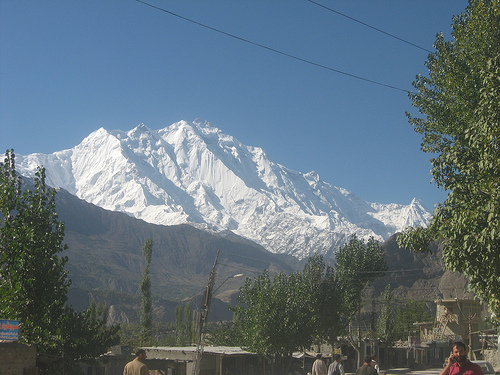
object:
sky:
[4, 0, 497, 204]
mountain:
[6, 116, 493, 295]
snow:
[272, 203, 353, 230]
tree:
[393, 23, 498, 277]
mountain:
[1, 282, 431, 333]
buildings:
[320, 319, 408, 373]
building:
[117, 333, 273, 373]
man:
[118, 348, 152, 374]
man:
[308, 353, 328, 374]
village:
[1, 297, 498, 374]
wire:
[120, 0, 400, 93]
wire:
[294, 0, 442, 56]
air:
[12, 3, 437, 184]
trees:
[189, 249, 224, 337]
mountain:
[166, 110, 456, 241]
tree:
[2, 147, 74, 322]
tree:
[21, 298, 123, 370]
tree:
[337, 235, 392, 331]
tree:
[222, 268, 326, 374]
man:
[437, 339, 484, 374]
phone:
[447, 350, 460, 362]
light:
[229, 271, 246, 282]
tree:
[135, 229, 157, 340]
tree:
[61, 307, 127, 372]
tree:
[305, 248, 345, 356]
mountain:
[22, 181, 499, 362]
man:
[350, 354, 379, 374]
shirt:
[445, 357, 482, 373]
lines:
[125, 0, 437, 99]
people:
[322, 352, 344, 374]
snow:
[173, 134, 276, 202]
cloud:
[5, 69, 99, 107]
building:
[379, 288, 494, 374]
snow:
[82, 147, 114, 163]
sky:
[8, 10, 169, 105]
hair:
[136, 347, 140, 359]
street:
[409, 365, 449, 370]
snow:
[120, 137, 153, 162]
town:
[2, 254, 498, 375]